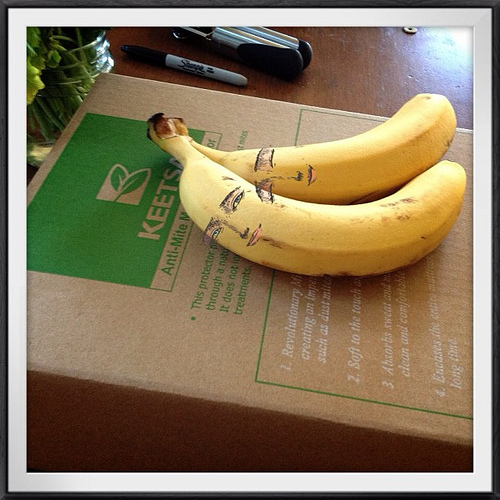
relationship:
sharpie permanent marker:
[169, 40, 209, 87] [119, 37, 245, 97]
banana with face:
[179, 165, 441, 278] [206, 183, 271, 254]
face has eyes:
[206, 183, 271, 254] [200, 180, 251, 248]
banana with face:
[215, 90, 460, 193] [242, 139, 332, 197]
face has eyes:
[242, 139, 332, 197] [235, 134, 293, 202]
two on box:
[156, 96, 446, 274] [64, 150, 210, 340]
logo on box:
[50, 100, 182, 303] [64, 150, 210, 340]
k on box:
[132, 215, 172, 251] [64, 150, 210, 340]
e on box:
[145, 204, 174, 227] [64, 150, 210, 340]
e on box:
[149, 190, 173, 211] [64, 150, 210, 340]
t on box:
[153, 176, 180, 199] [64, 150, 210, 340]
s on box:
[154, 159, 188, 187] [64, 150, 210, 340]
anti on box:
[156, 244, 181, 282] [64, 150, 210, 340]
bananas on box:
[156, 96, 446, 274] [64, 150, 210, 340]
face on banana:
[206, 183, 271, 254] [179, 165, 441, 278]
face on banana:
[242, 139, 332, 197] [215, 90, 460, 193]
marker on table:
[119, 37, 245, 97] [325, 35, 452, 95]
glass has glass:
[31, 48, 108, 141] [25, 25, 114, 145]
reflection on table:
[419, 30, 469, 83] [325, 35, 452, 95]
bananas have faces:
[156, 96, 446, 274] [208, 129, 326, 269]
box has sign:
[64, 150, 210, 340] [50, 100, 182, 303]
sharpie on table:
[169, 40, 209, 87] [325, 35, 452, 95]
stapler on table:
[189, 13, 307, 81] [325, 35, 452, 95]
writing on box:
[292, 285, 450, 380] [64, 150, 210, 340]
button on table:
[380, 17, 419, 38] [325, 35, 452, 95]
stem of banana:
[143, 101, 192, 159] [179, 165, 441, 278]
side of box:
[44, 341, 360, 459] [64, 150, 210, 340]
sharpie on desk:
[169, 40, 209, 87] [336, 43, 402, 97]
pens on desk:
[223, 24, 282, 47] [336, 43, 402, 97]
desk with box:
[336, 43, 402, 97] [64, 150, 210, 340]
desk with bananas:
[336, 43, 402, 97] [156, 96, 446, 274]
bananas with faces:
[156, 96, 446, 274] [208, 129, 326, 269]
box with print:
[64, 150, 210, 340] [100, 252, 288, 341]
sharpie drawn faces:
[169, 40, 209, 87] [208, 129, 326, 269]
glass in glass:
[25, 25, 114, 145] [31, 48, 108, 141]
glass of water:
[31, 48, 108, 141] [28, 132, 70, 167]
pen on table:
[119, 37, 245, 97] [325, 35, 452, 95]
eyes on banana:
[200, 180, 251, 248] [179, 165, 441, 278]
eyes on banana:
[235, 134, 293, 202] [215, 90, 460, 193]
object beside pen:
[189, 13, 307, 81] [119, 37, 245, 97]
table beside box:
[325, 35, 452, 95] [64, 150, 210, 340]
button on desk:
[380, 17, 419, 38] [336, 43, 402, 97]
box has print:
[64, 150, 210, 340] [100, 252, 288, 341]